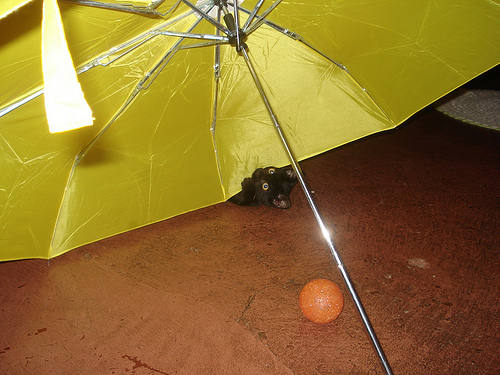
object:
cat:
[230, 166, 305, 207]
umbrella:
[1, 0, 500, 375]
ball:
[299, 279, 345, 324]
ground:
[0, 106, 500, 374]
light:
[321, 228, 331, 241]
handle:
[242, 43, 396, 374]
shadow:
[78, 130, 104, 165]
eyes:
[261, 182, 269, 191]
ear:
[282, 168, 305, 183]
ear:
[272, 191, 291, 209]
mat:
[434, 89, 500, 132]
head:
[252, 166, 306, 208]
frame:
[40, 0, 95, 134]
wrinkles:
[103, 42, 154, 79]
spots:
[121, 354, 165, 373]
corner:
[329, 2, 467, 99]